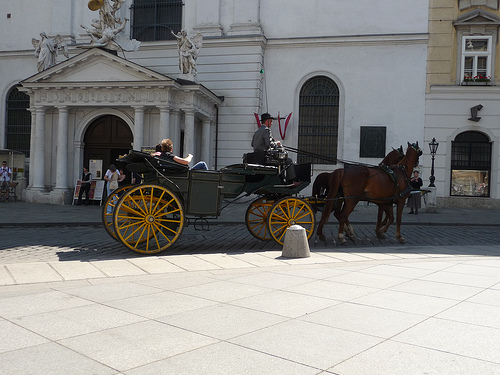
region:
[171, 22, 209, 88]
statue in the building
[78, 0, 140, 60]
statue in the building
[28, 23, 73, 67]
statue in the building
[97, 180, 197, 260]
yellow wheels of a cart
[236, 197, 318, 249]
yellow wheels of a cart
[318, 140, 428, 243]
a horse pulling a cart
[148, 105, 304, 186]
men on a cart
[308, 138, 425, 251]
two horses pulling a cart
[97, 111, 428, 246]
this is a chariot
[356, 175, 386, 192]
the fur is brown in color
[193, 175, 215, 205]
the chariot is black in color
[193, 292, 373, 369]
this is the ground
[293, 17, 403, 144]
this is a building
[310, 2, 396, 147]
the building is tall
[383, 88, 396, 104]
the walls are white in color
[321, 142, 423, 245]
these are two horses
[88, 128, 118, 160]
this is a door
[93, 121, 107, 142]
the door is wooden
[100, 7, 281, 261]
people in a carriage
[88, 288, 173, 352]
it is a sunny day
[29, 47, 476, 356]
picture taken during the day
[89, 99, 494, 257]
the carriage is being pulled by two horses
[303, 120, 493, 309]
the horses are brown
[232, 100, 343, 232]
a man is holding the reins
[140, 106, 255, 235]
two people are in the carriage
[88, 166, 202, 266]
the wheels are yellow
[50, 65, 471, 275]
picture taken outdoors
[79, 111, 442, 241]
the carriage is on the street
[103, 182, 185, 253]
Yellow and black wheels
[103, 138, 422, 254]
Horse carriage on stick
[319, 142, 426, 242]
Two big brown horses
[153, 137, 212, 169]
People sitting on carriage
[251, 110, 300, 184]
Man holding horse ropes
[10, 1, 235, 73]
White statues on building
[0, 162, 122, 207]
People standing on street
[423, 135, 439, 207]
Street light on stand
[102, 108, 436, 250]
Two horses pulling carriage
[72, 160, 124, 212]
People in front of building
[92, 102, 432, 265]
a horse drawn carriage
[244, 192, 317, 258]
the front wheels of the carriage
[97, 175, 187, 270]
the back wheels of the carriage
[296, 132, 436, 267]
the two horses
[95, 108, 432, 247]
2 horses pulling a carriage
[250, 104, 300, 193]
the driver of the carriage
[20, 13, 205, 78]
three statues on the roof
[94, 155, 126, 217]
a lady digging through her purse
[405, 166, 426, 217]
a lady standing next to a streetlight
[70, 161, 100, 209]
a man standing by the sign at the front door